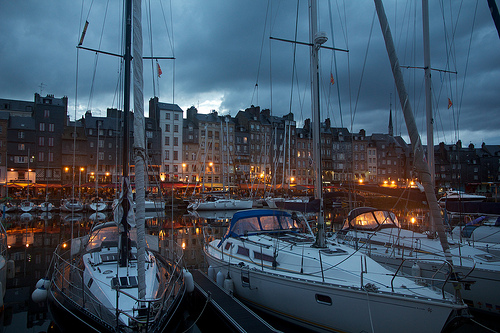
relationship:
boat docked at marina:
[200, 210, 463, 331] [13, 160, 495, 302]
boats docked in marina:
[199, 0, 469, 333] [6, 168, 498, 330]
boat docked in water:
[200, 210, 463, 331] [6, 213, 47, 288]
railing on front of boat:
[131, 0, 147, 309] [56, 211, 187, 328]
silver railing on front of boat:
[389, 251, 459, 303] [200, 210, 463, 331]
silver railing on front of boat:
[389, 251, 459, 303] [339, 205, 499, 296]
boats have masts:
[0, 2, 499, 332] [64, 4, 481, 324]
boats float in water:
[58, 201, 498, 330] [9, 225, 37, 250]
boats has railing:
[32, 0, 196, 332] [131, 0, 147, 309]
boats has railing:
[199, 0, 469, 333] [131, 0, 147, 309]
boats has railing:
[334, 203, 500, 309] [131, 0, 147, 309]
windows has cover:
[221, 211, 309, 232] [224, 206, 306, 237]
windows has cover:
[348, 211, 405, 228] [224, 206, 306, 237]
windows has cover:
[164, 148, 169, 160] [224, 206, 306, 237]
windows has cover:
[172, 148, 179, 161] [224, 206, 306, 237]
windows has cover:
[348, 211, 405, 228] [341, 203, 402, 231]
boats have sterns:
[54, 34, 175, 317] [21, 201, 168, 225]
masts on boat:
[308, 0, 333, 247] [189, 198, 459, 315]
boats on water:
[53, 168, 475, 303] [26, 188, 459, 228]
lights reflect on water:
[0, 160, 451, 253] [155, 190, 407, 255]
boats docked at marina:
[334, 203, 500, 309] [6, 168, 498, 330]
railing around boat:
[34, 236, 213, 329] [7, 91, 229, 331]